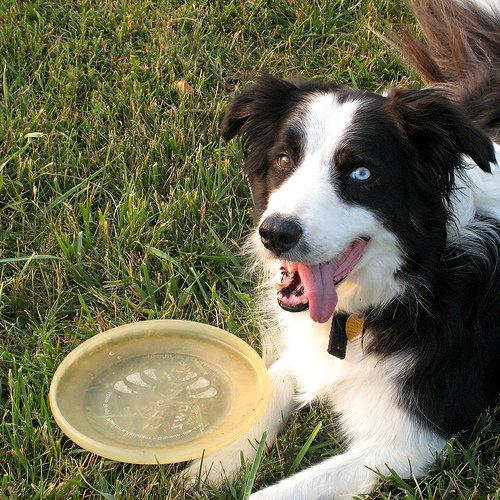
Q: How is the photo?
A: Clear.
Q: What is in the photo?
A: A dog.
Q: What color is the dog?
A: Black and white.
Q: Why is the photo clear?
A: Its during the day.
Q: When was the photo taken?
A: Daytime.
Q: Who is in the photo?
A: Nobody.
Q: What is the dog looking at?
A: The camera.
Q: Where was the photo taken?
A: In a park.